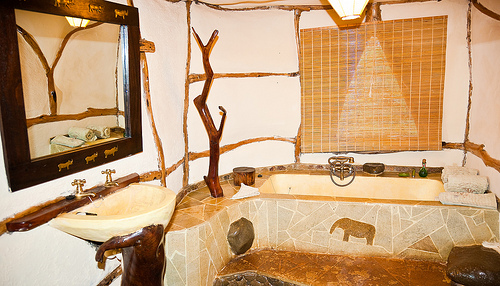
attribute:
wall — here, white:
[16, 8, 495, 207]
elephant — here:
[318, 217, 386, 244]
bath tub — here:
[246, 163, 463, 252]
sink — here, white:
[53, 184, 181, 243]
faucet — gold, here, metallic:
[72, 171, 97, 202]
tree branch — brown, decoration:
[190, 20, 231, 201]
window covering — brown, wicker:
[293, 10, 459, 164]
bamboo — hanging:
[296, 9, 454, 164]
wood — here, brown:
[92, 221, 168, 282]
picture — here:
[3, 4, 494, 282]